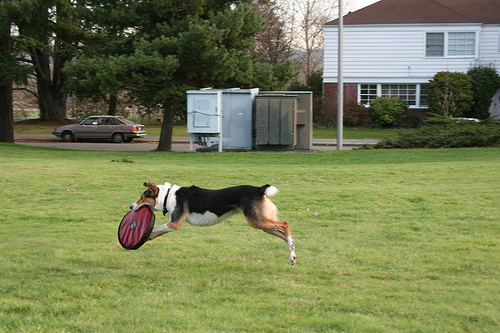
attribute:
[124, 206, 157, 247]
frisbee — red, thick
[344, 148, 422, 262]
grass — green, full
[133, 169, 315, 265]
dog — jumping, playing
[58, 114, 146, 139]
car — old, brown, parked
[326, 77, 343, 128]
bricks — red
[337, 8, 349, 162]
pole — concrete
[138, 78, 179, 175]
tree — evergreen, green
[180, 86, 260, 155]
box — big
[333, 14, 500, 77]
house — white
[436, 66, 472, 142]
bush — big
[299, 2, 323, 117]
tree — tall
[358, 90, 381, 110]
windows — white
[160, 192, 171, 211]
collar — black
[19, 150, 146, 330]
lawn — green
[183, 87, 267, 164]
dumpster — white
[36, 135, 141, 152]
street — grey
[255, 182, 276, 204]
tail — white, short, small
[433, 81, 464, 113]
tree — bushy